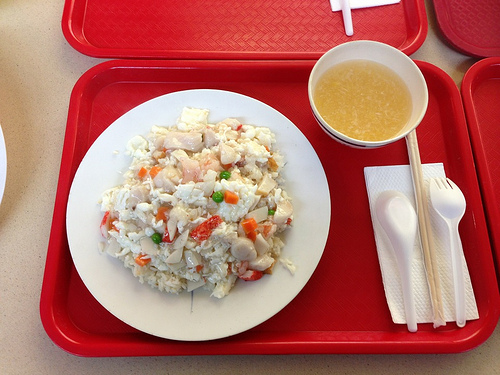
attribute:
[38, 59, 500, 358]
tray — red, plastic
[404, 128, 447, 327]
chop sticks — wooden,  two, for chop, wood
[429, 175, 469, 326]
spork — cafeterian, white, plastic, disposable.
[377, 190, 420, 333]
spoon — asian style, shiny, disposable, plastic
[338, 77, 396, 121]
soup — egg drop, chicken noodle, serving, egg foo, asian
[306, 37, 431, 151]
bowl — white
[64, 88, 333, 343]
plate — round, plastic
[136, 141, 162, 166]
rice — fried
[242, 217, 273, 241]
carrots — red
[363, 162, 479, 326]
napkin — white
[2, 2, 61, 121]
table — white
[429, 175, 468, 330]
fork — plastic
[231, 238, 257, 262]
scallop — small